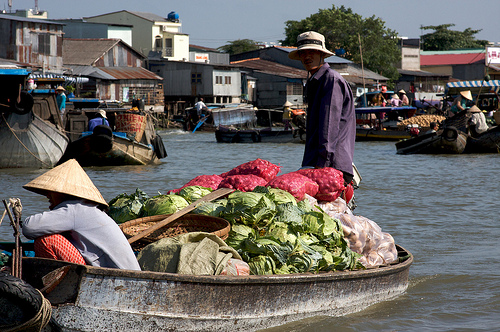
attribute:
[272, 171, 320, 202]
bag — red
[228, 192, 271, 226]
cabbage — green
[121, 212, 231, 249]
basket — woven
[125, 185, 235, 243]
oar — wooden, straight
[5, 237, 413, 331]
boat — filled, old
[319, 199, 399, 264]
bag — white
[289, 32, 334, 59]
hat — cream, australian, white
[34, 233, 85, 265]
pants — orange, red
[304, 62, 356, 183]
shirt — blue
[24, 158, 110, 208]
hat — triangular, straw, conical, pointed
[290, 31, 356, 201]
man — standing, steering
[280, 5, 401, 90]
tree — large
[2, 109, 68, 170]
boat — white, gray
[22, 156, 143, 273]
woman — crouched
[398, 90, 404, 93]
hat — distant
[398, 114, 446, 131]
potatoes — piled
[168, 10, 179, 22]
person — mending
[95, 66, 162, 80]
roof — rusty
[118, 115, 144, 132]
letters — red